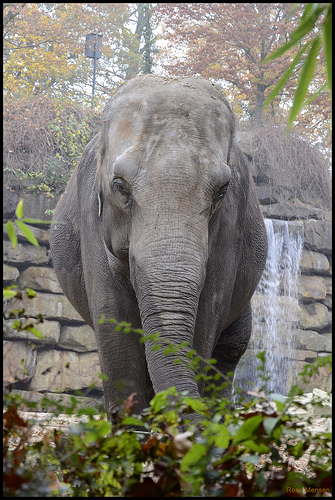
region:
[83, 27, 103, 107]
a sign on a post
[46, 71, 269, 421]
an elephant standing by a bush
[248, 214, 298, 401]
a waterfall over some rocks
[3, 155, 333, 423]
a wall made of white stones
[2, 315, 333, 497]
a bush of green and brown leaves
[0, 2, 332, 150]
orange trees on top of a hill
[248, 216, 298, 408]
a small wall of water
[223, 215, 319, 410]
waterfall pouring from the rocks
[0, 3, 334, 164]
orange and gold leaves indicate the Autumn season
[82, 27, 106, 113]
box on a post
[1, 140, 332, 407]
rock wall enclosing the elephant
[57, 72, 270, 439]
elephant in a zoo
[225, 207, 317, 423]
manmade waterfall behind elephant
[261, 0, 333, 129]
bamboo leaves hanging down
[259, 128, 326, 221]
dry, bare vines hang over the rock enclosure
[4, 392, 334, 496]
various plants with brown and green leaves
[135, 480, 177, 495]
A couple of brown leaves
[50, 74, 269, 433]
A very large grey elephant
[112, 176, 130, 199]
The right eye of the elephant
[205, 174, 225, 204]
The left eye of the elephant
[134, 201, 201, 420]
The large trunk of the elephant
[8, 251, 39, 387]
A wall made of rock in the distance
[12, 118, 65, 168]
Vines growing down the wall of rock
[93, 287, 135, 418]
The right leg of the elephant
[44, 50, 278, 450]
a large elephant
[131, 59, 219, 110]
a elephant with dirt on it's head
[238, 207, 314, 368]
a water fall made of rocks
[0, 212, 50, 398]
a rock wall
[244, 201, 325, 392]
a rock wall with a waterfall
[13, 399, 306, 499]
brown leaves on the ground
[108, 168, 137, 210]
a elephants eye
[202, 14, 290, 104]
a tree with brown and yellow leaves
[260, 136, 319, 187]
brown vines on rocks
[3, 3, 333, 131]
light of daytime sky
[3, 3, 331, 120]
autumn leaves on trees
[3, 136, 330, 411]
stones in enclosure wall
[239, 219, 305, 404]
waterfall in front of stone wall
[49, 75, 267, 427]
front of standing elephant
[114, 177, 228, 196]
eyes on elephant head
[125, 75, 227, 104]
dirt on elephant head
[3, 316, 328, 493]
green leaves in foreground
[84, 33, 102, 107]
box on metal pole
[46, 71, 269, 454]
a large wild elephant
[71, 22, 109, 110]
a sign in the woods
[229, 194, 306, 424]
a waterfall spilling off of a cliff